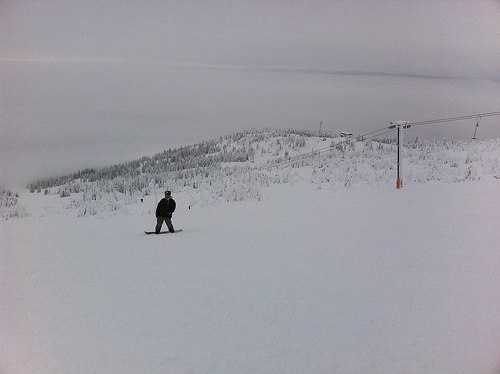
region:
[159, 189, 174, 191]
Person wearing black hat.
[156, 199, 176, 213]
Person wearing black coat.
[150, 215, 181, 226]
Person wearing gray pants.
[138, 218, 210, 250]
Person standing on snow board.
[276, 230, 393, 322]
Snow is covering ground.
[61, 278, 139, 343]
Snow on ground is white.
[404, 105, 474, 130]
Wires connected to pole.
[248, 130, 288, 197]
Trees on side of hill.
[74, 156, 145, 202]
Trees on side of hill.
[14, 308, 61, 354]
Snow covering the ground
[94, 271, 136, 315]
Snow covering the ground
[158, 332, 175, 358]
Snow covering the ground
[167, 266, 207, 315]
Snow covering the ground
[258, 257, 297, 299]
Snow covering the ground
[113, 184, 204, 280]
PErson in the snow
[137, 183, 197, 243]
A snowboarder on a slope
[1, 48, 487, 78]
white and pale line between sky and snow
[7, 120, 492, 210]
curved slope covered in snow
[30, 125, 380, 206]
upright stubble of trees in snow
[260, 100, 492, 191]
pole and wires toward top of slope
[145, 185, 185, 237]
dark silhouette of snowboarder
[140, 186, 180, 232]
legs apart on board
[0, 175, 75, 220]
clear path through snow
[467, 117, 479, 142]
tower in distance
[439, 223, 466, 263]
white snow on ground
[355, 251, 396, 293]
white snow on ground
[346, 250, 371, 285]
white snow on ground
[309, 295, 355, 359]
white snow on ground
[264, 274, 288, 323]
white snow on ground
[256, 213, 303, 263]
white snow on ground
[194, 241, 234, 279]
white snow on ground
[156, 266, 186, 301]
white snow on ground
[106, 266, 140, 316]
white snow on ground